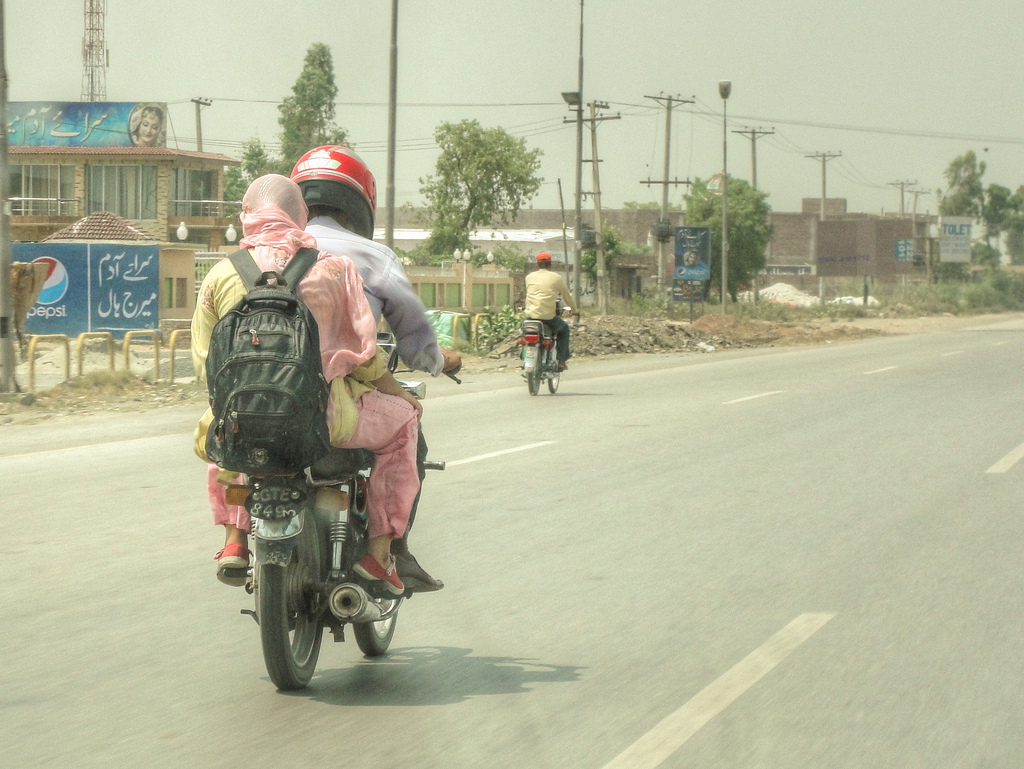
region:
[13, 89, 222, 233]
a house on a street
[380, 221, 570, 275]
a house on a street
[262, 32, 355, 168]
a tree in a city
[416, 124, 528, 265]
a tree in a city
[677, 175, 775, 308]
a tree in a city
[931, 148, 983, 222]
a tree in a city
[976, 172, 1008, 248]
a tree in a city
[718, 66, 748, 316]
a light pole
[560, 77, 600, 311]
a light pole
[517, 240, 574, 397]
The man is on a silver bike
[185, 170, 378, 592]
The woman has on a black backpack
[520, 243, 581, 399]
The man has on a red hat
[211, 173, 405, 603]
The woman has on red shoes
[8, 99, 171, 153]
There is a woman on the sign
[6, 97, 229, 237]
There is a sign above a building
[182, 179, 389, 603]
The woman has on a pink head wrap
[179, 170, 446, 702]
There is two people on the motorcycle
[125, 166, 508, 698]
there is a man and woman on the motorcycle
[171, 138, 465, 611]
two people riding a motorcycle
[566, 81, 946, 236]
a line of power poles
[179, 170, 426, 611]
a woman dressed in pink riding a motorcycle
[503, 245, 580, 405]
a man wearing a white shirt on a motorcycle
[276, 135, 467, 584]
a man wearing a red helmet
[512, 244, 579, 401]
a man wearing a red cap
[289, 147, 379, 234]
large round red bike helmet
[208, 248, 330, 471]
small square cloth backpack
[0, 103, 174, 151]
long blue sign board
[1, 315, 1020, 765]
large wide cement road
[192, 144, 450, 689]
people riding on motor bike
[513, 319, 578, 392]
small metal framed motor bike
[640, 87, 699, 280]
large tall wooden pole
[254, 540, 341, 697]
large round rubber tire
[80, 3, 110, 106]
large tall metal tower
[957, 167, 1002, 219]
green leaves on the tree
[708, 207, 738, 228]
green leaves on the tree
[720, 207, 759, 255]
green leaves on the tree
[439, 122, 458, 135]
green leaves on the tree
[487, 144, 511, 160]
green leaves on the tree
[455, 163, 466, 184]
green leaves on the tree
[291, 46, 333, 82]
green leaves on the tree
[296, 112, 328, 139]
green leaves on the tree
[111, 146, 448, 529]
the people are riding a motorcycle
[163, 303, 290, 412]
the backpack is black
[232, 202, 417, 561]
the woman is wearing pink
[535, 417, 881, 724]
the street is paved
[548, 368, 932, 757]
the street is light gray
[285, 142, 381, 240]
red helmet on person's head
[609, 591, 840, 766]
white line on road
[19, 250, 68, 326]
pepsi logo on sign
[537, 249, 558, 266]
red hat on man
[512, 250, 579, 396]
man on a motorcycle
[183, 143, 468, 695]
man and a woman on a motorcycle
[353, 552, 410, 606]
red shoe on woman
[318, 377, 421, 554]
pink pants on woman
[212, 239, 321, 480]
black backpack on woman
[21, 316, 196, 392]
yellow metal fence poles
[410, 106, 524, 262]
A tree in a city.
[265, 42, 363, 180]
A tree in a city.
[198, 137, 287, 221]
A tree in a city.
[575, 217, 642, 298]
A tree in a city.